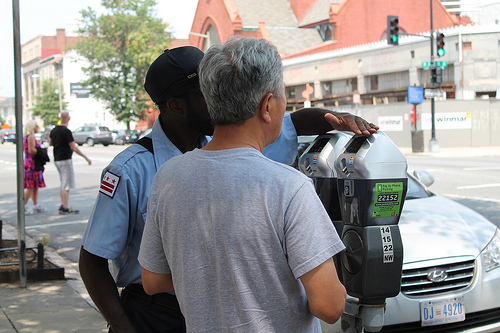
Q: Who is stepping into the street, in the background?
A: The couple.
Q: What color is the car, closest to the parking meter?
A: Silver.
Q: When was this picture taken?
A: During the day.